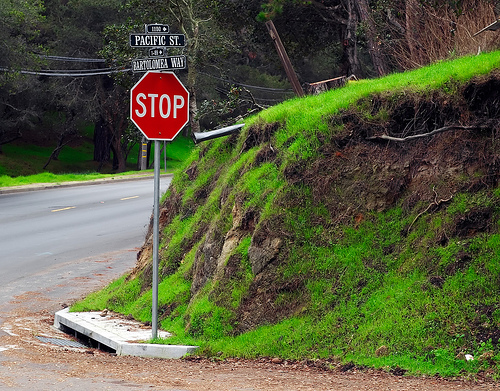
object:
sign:
[129, 52, 188, 75]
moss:
[229, 233, 255, 256]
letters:
[171, 92, 183, 121]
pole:
[148, 138, 165, 343]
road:
[0, 173, 198, 390]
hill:
[64, 50, 500, 379]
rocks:
[249, 216, 284, 276]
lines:
[48, 202, 79, 214]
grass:
[235, 50, 500, 161]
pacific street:
[127, 31, 189, 49]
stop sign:
[130, 70, 192, 143]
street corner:
[0, 265, 204, 363]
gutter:
[52, 304, 201, 359]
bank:
[125, 49, 500, 379]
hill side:
[146, 143, 500, 285]